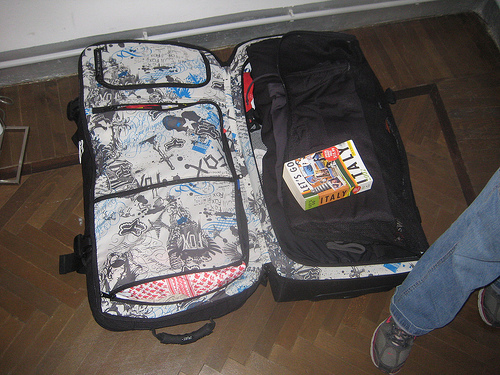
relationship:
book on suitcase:
[271, 137, 377, 213] [64, 26, 440, 346]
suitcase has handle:
[64, 26, 440, 346] [156, 316, 220, 347]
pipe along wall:
[2, 0, 431, 70] [1, 1, 482, 86]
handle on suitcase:
[156, 316, 220, 347] [64, 26, 440, 346]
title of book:
[335, 144, 369, 187] [271, 137, 377, 213]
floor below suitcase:
[2, 10, 500, 374] [64, 26, 440, 346]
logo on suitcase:
[185, 148, 228, 183] [64, 26, 440, 346]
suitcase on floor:
[64, 26, 440, 346] [2, 10, 500, 374]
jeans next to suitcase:
[382, 162, 499, 339] [64, 26, 440, 346]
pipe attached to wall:
[2, 0, 431, 70] [1, 1, 482, 86]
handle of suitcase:
[156, 316, 220, 347] [64, 26, 440, 346]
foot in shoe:
[370, 323, 410, 366] [368, 302, 417, 372]